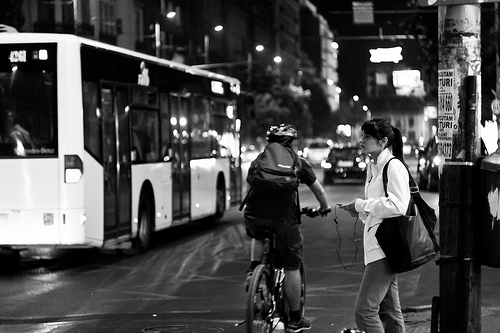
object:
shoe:
[282, 316, 311, 332]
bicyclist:
[242, 122, 330, 332]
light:
[211, 24, 226, 32]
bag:
[374, 156, 437, 274]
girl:
[338, 118, 414, 331]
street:
[0, 149, 499, 332]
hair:
[358, 116, 408, 171]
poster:
[436, 68, 460, 159]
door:
[98, 81, 121, 237]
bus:
[0, 24, 242, 254]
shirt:
[351, 145, 412, 267]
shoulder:
[374, 153, 403, 168]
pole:
[434, 0, 485, 332]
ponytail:
[387, 124, 411, 169]